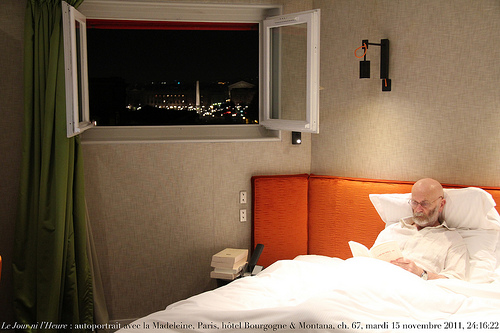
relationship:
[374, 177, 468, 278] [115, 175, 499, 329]
man reading in bed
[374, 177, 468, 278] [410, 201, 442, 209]
man wearing spectacles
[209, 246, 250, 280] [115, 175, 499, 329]
books stacked on side of bed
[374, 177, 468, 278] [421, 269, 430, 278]
man wearing a watch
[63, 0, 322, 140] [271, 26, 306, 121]
window with glass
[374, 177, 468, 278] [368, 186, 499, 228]
man using pillow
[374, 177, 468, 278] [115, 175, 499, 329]
man in bed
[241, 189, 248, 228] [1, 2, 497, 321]
outlets on wall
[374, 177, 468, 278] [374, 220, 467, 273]
man wearing a white shirt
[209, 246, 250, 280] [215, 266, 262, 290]
books on side table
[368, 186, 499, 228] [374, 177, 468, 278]
pillow behind man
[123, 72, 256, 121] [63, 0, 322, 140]
city outside window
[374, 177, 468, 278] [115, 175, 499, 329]
man sitting in bed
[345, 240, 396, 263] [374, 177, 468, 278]
book being read by man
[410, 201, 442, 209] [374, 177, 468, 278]
spectacles worn by man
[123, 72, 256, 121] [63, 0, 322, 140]
city through window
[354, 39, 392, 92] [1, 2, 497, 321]
light on wall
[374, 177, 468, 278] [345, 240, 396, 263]
man reading a book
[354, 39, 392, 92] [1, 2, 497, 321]
light attached to wall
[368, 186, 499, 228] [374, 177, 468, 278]
pillow propped up behind man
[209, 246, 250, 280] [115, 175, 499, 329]
books by side of bed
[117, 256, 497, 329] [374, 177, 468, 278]
bed coverings over man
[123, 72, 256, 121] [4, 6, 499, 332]
city seen from room